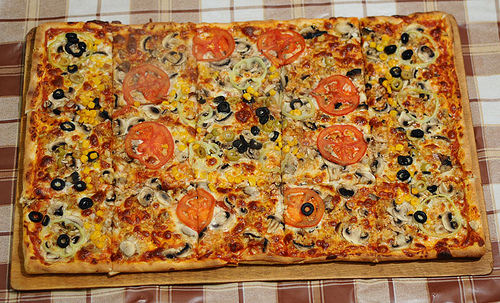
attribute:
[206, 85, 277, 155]
olives — black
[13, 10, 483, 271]
pizza — square, rectangular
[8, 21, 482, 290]
coaster — wooden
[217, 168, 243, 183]
topping — yellow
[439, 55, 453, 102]
sauce — red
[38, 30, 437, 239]
toppings — many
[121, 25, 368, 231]
tomatoes — many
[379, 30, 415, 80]
olives — black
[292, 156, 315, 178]
cheese — melted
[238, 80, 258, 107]
corn — pieces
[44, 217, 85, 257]
onions — circle pieces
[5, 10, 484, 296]
board — wooden, cutting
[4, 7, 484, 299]
table cloth — plaid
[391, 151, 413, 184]
olives — green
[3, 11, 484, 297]
tablecloth — plaid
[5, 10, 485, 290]
tray — brown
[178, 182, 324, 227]
tomatoes — red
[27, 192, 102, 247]
olives — black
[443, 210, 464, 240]
mushroom — light brown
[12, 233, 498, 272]
pizza crust — light brown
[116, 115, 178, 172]
tomato — thinly sliced, ripe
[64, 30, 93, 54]
black olive — slice